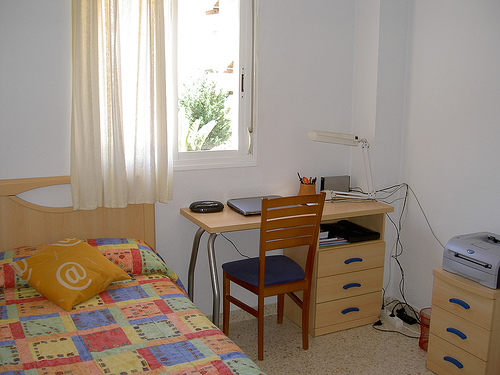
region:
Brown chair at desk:
[226, 195, 326, 348]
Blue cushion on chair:
[220, 254, 310, 282]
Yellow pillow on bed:
[9, 235, 132, 302]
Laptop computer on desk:
[231, 193, 286, 215]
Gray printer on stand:
[445, 230, 498, 283]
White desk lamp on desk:
[308, 130, 380, 202]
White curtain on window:
[71, 0, 169, 216]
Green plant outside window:
[181, 84, 236, 146]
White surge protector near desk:
[382, 303, 400, 330]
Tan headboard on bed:
[4, 178, 155, 245]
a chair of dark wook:
[224, 189, 326, 357]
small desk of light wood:
[184, 189, 391, 335]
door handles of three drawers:
[339, 254, 364, 316]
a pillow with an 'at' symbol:
[10, 233, 127, 311]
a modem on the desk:
[190, 199, 222, 213]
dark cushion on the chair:
[222, 252, 304, 287]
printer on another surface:
[443, 230, 498, 287]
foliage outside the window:
[178, 56, 237, 151]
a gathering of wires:
[380, 199, 422, 334]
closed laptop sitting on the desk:
[229, 194, 301, 214]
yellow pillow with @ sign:
[16, 230, 130, 307]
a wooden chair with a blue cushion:
[218, 189, 328, 364]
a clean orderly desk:
[180, 173, 391, 348]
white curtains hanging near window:
[65, 0, 182, 208]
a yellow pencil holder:
[293, 169, 319, 201]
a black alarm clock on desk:
[186, 194, 223, 219]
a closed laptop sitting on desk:
[225, 190, 305, 222]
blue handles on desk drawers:
[337, 249, 364, 323]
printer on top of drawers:
[439, 223, 497, 294]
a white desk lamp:
[306, 125, 382, 205]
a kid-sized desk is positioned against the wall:
[177, 171, 395, 360]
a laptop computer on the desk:
[223, 189, 301, 220]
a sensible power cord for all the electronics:
[373, 296, 421, 339]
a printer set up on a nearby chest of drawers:
[438, 223, 498, 290]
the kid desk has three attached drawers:
[311, 208, 389, 335]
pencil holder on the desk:
[292, 166, 319, 196]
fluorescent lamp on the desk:
[305, 123, 376, 204]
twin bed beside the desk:
[1, 171, 263, 371]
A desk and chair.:
[178, 189, 394, 363]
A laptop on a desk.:
[226, 193, 300, 217]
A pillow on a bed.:
[9, 235, 132, 313]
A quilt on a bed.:
[0, 236, 262, 372]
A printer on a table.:
[442, 230, 498, 291]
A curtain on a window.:
[69, 0, 179, 212]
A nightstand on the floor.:
[424, 266, 496, 373]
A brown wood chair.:
[223, 190, 328, 363]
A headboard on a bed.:
[0, 172, 157, 252]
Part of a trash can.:
[416, 305, 433, 353]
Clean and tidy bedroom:
[2, 1, 498, 372]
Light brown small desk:
[178, 188, 395, 341]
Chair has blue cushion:
[221, 190, 327, 362]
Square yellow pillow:
[8, 235, 133, 315]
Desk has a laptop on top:
[179, 185, 396, 338]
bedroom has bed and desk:
[0, 2, 499, 374]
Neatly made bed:
[0, 173, 261, 373]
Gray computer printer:
[441, 231, 499, 289]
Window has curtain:
[68, 0, 255, 212]